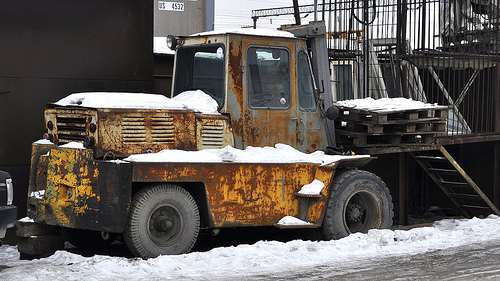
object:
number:
[156, 0, 183, 11]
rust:
[135, 162, 209, 181]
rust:
[203, 164, 337, 224]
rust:
[227, 41, 242, 102]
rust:
[98, 110, 194, 149]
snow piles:
[112, 138, 366, 164]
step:
[296, 178, 329, 201]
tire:
[320, 165, 403, 246]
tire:
[122, 179, 207, 264]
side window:
[237, 44, 302, 114]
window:
[249, 45, 293, 112]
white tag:
[158, 1, 188, 11]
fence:
[314, 0, 499, 133]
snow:
[52, 82, 372, 180]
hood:
[38, 85, 233, 168]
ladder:
[409, 143, 498, 216]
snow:
[0, 214, 497, 281]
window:
[244, 45, 290, 110]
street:
[0, 196, 498, 281]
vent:
[119, 113, 174, 143]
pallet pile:
[334, 93, 455, 154]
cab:
[172, 28, 328, 153]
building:
[2, 2, 153, 237]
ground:
[0, 191, 481, 276]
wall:
[2, 0, 150, 231]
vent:
[194, 120, 229, 150]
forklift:
[11, 20, 393, 255]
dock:
[334, 94, 497, 160]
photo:
[9, 9, 494, 276]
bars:
[313, 0, 496, 134]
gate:
[311, 2, 496, 140]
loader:
[11, 23, 456, 266]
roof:
[166, 25, 315, 41]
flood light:
[164, 36, 180, 48]